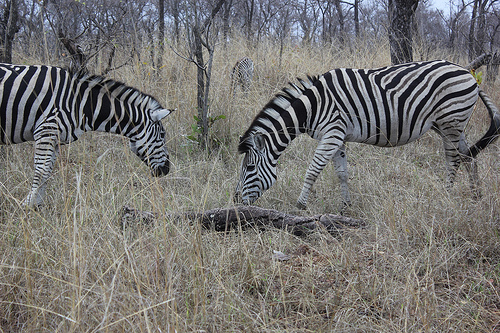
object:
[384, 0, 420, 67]
trees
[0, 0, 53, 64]
trees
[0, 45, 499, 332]
field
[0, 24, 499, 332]
grass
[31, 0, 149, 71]
trees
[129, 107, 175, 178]
head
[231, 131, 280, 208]
head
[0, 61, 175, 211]
animal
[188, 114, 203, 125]
leaves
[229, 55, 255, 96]
zebra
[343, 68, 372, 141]
stripes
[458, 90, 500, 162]
tail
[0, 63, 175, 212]
zebra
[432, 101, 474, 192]
leg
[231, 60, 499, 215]
zebra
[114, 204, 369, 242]
log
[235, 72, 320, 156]
mane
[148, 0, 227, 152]
trees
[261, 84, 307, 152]
neck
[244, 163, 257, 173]
eye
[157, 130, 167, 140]
eye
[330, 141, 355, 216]
leg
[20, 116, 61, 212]
leg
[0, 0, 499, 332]
wild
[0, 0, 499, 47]
sky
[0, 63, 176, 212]
fur